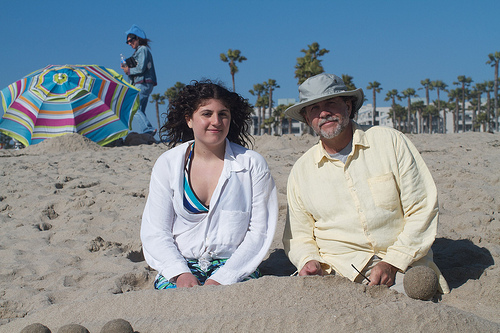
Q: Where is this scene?
A: Beach.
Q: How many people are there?
A: Three.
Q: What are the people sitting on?
A: Sand.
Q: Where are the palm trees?
A: Behind the people.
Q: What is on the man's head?
A: Hat.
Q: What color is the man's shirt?
A: Yellow.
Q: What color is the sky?
A: Blue.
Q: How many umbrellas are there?
A: One.